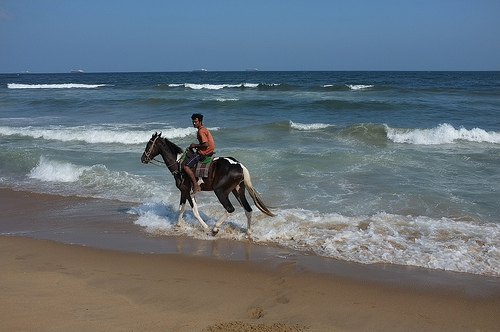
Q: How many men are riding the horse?
A: One.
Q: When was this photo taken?
A: Daytime.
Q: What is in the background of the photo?
A: Ocean.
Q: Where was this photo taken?
A: Beach.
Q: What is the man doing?
A: Riding a horse.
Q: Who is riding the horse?
A: A man.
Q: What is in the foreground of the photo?
A: Sand.